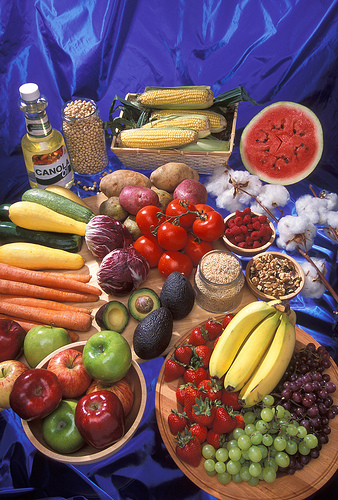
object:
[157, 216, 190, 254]
food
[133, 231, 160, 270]
tomatos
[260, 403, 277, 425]
grapes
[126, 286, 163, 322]
avocado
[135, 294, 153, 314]
seed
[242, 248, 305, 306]
bowl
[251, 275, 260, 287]
walnuts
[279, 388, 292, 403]
grapes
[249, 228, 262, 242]
raspberries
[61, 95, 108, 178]
jar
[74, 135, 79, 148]
nuts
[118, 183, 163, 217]
potato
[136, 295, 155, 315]
pit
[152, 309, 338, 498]
tray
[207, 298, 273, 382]
banana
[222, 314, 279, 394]
banana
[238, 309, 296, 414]
banana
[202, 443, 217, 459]
grape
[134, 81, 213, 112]
corn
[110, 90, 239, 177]
basket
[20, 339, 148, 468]
bowl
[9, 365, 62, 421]
apple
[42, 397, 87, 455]
apple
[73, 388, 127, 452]
apple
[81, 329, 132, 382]
apple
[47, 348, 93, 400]
apple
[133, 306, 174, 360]
avocado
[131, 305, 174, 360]
skin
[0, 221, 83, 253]
squash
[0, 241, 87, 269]
squash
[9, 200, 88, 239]
squash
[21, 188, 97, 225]
squash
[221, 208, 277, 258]
bowl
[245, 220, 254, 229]
raspberry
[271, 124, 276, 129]
seed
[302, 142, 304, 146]
seed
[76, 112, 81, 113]
bean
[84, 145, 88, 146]
bean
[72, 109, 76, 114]
bean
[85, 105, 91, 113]
bean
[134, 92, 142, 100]
cob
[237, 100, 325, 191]
watermelon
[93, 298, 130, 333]
avocado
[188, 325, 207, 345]
strawberry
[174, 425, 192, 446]
stem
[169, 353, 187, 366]
stem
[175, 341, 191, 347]
stem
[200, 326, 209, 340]
stem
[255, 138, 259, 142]
seed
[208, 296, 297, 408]
bunch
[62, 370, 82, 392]
skin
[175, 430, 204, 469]
strawberries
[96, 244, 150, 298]
radicchio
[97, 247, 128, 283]
leaves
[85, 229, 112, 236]
veins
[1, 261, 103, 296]
vegetable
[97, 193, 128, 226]
vegetable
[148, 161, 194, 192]
vegetable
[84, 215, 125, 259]
vegetable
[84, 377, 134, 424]
apples